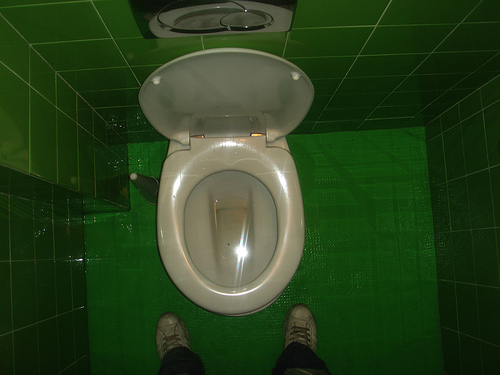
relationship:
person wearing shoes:
[141, 303, 338, 374] [152, 308, 320, 345]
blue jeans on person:
[166, 347, 328, 374] [156, 302, 332, 374]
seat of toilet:
[83, 58, 367, 322] [135, 43, 327, 323]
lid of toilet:
[136, 42, 318, 144] [135, 43, 327, 323]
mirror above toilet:
[145, 7, 295, 43] [135, 43, 327, 323]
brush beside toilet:
[120, 169, 161, 203] [135, 43, 327, 323]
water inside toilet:
[177, 192, 273, 286] [135, 43, 327, 323]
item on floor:
[340, 187, 415, 297] [99, 159, 154, 308]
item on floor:
[340, 187, 415, 297] [309, 145, 430, 271]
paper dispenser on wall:
[117, 2, 302, 44] [117, 12, 431, 73]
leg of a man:
[150, 313, 206, 373] [122, 297, 348, 374]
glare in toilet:
[228, 240, 270, 268] [124, 41, 338, 328]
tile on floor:
[80, 128, 434, 370] [112, 181, 462, 370]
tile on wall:
[367, 0, 429, 62] [415, 111, 498, 274]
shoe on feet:
[280, 302, 318, 355] [131, 297, 363, 370]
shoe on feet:
[155, 310, 190, 364] [131, 297, 363, 370]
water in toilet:
[211, 192, 253, 272] [140, 47, 315, 317]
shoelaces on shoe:
[288, 324, 313, 347] [280, 302, 318, 355]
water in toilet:
[211, 192, 253, 272] [135, 43, 327, 323]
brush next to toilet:
[126, 169, 161, 204] [135, 43, 327, 323]